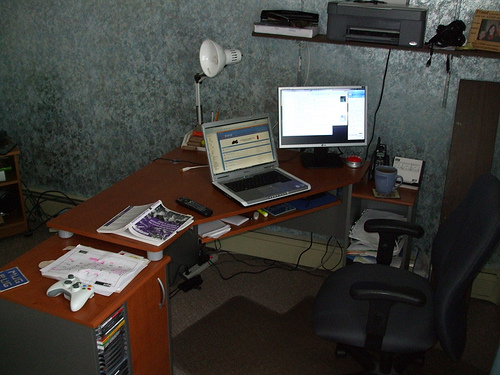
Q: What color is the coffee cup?
A: Blue.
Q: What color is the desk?
A: Brown.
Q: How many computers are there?
A: Two.